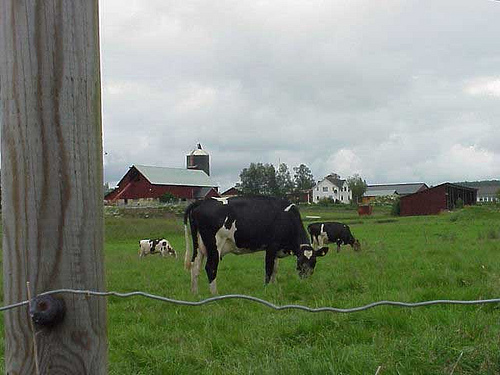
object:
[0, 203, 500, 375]
grass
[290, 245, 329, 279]
head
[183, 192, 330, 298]
cow